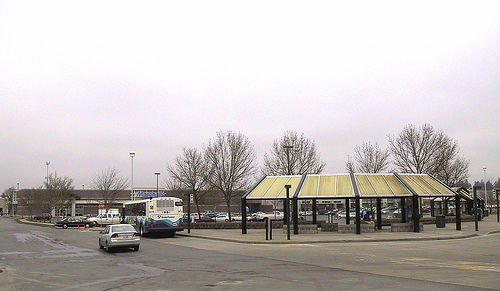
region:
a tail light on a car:
[107, 226, 118, 246]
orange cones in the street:
[73, 217, 91, 236]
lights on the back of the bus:
[147, 209, 160, 230]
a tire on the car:
[61, 211, 72, 234]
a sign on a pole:
[185, 186, 198, 212]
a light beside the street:
[149, 160, 164, 193]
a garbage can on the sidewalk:
[431, 206, 450, 235]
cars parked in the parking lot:
[190, 193, 229, 225]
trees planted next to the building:
[29, 178, 66, 228]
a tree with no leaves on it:
[206, 138, 242, 221]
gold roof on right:
[252, 180, 454, 215]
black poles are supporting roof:
[222, 191, 454, 235]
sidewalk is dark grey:
[213, 241, 384, 289]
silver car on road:
[90, 216, 144, 260]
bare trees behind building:
[140, 146, 465, 221]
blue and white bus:
[125, 193, 179, 245]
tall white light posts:
[45, 148, 155, 205]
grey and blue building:
[10, 163, 236, 232]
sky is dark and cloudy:
[83, 1, 282, 119]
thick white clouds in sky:
[30, 1, 317, 116]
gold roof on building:
[242, 169, 458, 224]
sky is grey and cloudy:
[237, 0, 438, 148]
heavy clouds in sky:
[294, 18, 393, 96]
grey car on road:
[95, 209, 139, 261]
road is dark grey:
[247, 248, 384, 289]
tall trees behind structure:
[190, 118, 440, 243]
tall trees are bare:
[165, 124, 464, 241]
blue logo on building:
[120, 184, 173, 204]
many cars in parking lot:
[65, 200, 308, 232]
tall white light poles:
[17, 141, 194, 231]